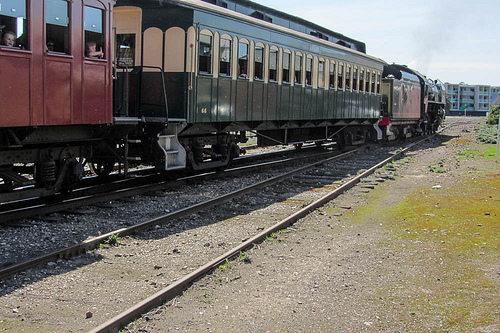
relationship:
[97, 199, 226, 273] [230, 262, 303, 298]
tracks on ground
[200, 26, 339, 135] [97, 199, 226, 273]
train on tracks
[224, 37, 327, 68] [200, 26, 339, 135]
windows on train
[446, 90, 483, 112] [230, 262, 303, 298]
building on ground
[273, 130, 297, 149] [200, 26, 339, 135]
feet of train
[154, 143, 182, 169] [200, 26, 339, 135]
stairs on train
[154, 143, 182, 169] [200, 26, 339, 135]
stairs of train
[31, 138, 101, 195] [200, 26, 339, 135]
wheels of train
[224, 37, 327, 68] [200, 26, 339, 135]
windows of train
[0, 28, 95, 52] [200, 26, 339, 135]
kids on train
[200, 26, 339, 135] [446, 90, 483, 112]
train past building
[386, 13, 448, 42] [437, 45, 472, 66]
sky has clouds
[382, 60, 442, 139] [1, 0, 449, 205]
engine powering train